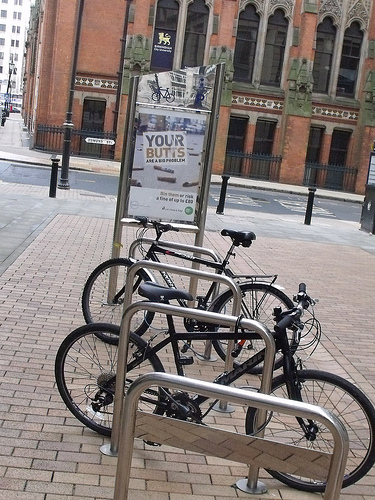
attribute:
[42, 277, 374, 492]
bike — parked, large, metal, standing up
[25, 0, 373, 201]
building — red brick, stone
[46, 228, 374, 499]
bikes — parked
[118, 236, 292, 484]
racks — metallic, silver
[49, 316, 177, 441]
wheel — black, large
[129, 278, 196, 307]
seat — black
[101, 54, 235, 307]
support — metallic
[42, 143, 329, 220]
fence — metal, black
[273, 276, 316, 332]
handlebars — black, rubber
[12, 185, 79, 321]
sidewalk — cobblestone, bricked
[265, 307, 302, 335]
handle — black, rubber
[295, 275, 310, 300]
handle — rubber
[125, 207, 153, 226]
handle — rubber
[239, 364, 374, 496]
wheel — large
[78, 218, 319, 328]
bike — chained, black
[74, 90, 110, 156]
door — long, glass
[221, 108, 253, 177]
door — long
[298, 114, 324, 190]
door — glass, long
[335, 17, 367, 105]
window — long, glass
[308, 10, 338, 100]
window — glass, long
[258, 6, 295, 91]
window — long, glass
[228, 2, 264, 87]
window — glass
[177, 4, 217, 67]
window — glass, long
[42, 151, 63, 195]
post — metal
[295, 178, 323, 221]
post — black